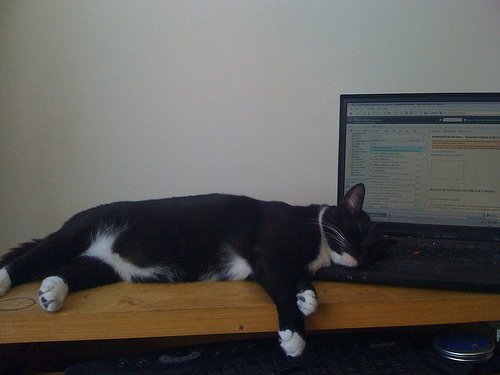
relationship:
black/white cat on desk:
[0, 182, 405, 360] [1, 247, 496, 361]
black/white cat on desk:
[0, 182, 405, 360] [4, 267, 499, 365]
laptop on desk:
[311, 92, 498, 295] [1, 276, 498, 346]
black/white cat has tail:
[0, 182, 405, 360] [2, 234, 52, 269]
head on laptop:
[324, 181, 402, 273] [311, 90, 500, 295]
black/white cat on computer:
[0, 182, 405, 360] [310, 91, 498, 298]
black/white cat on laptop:
[0, 182, 405, 360] [311, 90, 500, 295]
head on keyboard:
[310, 172, 382, 275] [326, 234, 498, 266]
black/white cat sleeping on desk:
[0, 182, 405, 360] [0, 267, 496, 345]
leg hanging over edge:
[250, 253, 307, 356] [89, 302, 489, 362]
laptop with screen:
[311, 90, 500, 295] [347, 102, 499, 226]